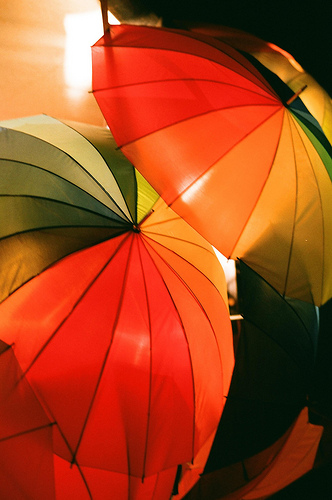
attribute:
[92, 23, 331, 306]
umbrella — open, orange, color, colored, green, red, yellow, black, white, grey, colorful, large, dark, small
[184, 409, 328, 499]
floor — wooden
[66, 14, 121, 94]
light — bright, shining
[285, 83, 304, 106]
top — metal